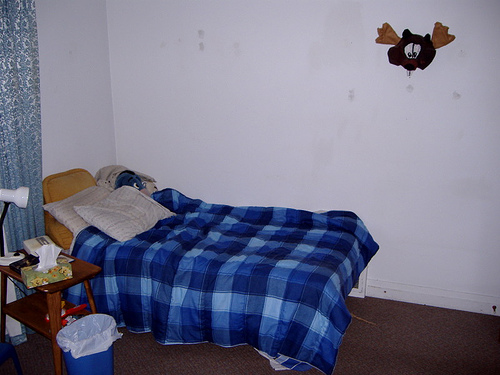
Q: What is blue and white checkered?
A: Blanet.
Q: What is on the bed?
A: Pillows.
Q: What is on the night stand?
A: Tissues.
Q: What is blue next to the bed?
A: Wastebasket.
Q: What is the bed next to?
A: White walls.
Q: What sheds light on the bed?
A: Lamp.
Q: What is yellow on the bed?
A: Pillow.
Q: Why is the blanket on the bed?
A: Keep warm.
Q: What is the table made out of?
A: Wood.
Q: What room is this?
A: The bedroom.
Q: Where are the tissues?
A: In a box on the table next to the bed.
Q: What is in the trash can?
A: A white plastic bag.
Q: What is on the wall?
A: A fabric moose head.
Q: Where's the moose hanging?
A: On wall.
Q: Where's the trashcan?
A: Next to bed.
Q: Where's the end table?
A: Next to bed.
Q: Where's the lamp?
A: On nightstand.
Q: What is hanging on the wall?
A: A moose head.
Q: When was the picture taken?
A: At daytime.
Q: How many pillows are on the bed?
A: Two.